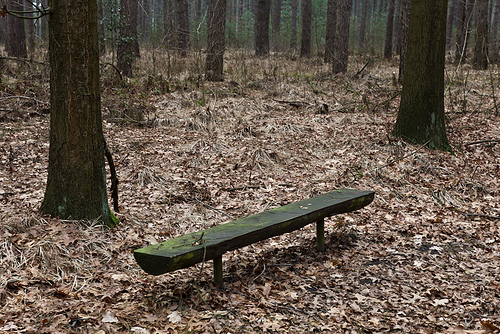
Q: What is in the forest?
A: A bench.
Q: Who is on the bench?
A: No one.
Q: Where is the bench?
A: In the forest.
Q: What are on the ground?
A: Leaves.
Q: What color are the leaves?
A: Brown.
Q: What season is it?
A: Fall.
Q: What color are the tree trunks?
A: Brown.